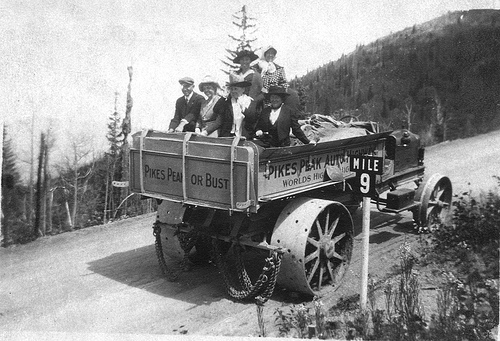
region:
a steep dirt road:
[2, 127, 498, 338]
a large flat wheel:
[263, 193, 355, 304]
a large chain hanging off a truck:
[208, 234, 274, 303]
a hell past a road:
[20, 5, 498, 228]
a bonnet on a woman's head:
[260, 46, 281, 64]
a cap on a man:
[174, 74, 196, 87]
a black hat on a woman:
[264, 83, 291, 97]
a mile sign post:
[348, 148, 382, 312]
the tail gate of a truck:
[127, 132, 262, 213]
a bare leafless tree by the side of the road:
[59, 133, 91, 234]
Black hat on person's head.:
[266, 85, 284, 104]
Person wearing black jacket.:
[274, 118, 313, 150]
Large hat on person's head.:
[227, 70, 247, 90]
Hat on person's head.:
[199, 74, 216, 93]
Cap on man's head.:
[173, 66, 202, 106]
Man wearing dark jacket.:
[172, 102, 199, 128]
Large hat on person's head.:
[229, 45, 260, 70]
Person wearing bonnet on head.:
[257, 43, 282, 72]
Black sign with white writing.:
[344, 150, 377, 206]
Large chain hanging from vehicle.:
[148, 218, 305, 296]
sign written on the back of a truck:
[135, 150, 246, 206]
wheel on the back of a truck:
[255, 197, 360, 307]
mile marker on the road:
[349, 150, 381, 203]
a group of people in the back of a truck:
[159, 41, 321, 181]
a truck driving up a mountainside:
[108, 15, 465, 330]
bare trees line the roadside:
[18, 80, 139, 220]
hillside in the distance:
[347, 18, 464, 112]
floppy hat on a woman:
[233, 39, 257, 70]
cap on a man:
[181, 73, 196, 94]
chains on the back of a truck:
[206, 240, 302, 310]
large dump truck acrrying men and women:
[129, 35, 453, 301]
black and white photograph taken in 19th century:
[5, 0, 496, 327]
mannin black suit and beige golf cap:
[169, 73, 202, 136]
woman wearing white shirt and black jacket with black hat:
[246, 85, 316, 145]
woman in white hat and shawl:
[193, 75, 229, 137]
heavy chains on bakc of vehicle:
[203, 238, 280, 306]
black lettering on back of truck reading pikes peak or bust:
[136, 157, 233, 194]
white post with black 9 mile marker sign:
[347, 152, 384, 323]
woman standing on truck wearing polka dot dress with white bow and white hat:
[254, 42, 291, 92]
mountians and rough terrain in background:
[6, 5, 495, 239]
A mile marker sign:
[348, 153, 382, 198]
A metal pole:
[358, 196, 370, 305]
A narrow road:
[0, 132, 497, 339]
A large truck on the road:
[123, 104, 455, 304]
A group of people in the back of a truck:
[156, 41, 320, 151]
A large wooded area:
[0, 10, 497, 245]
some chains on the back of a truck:
[151, 223, 282, 305]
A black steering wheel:
[338, 110, 358, 126]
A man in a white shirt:
[165, 73, 205, 133]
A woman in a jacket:
[251, 83, 314, 152]